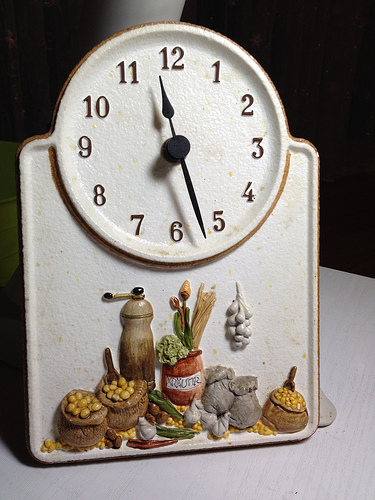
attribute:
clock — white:
[29, 44, 320, 455]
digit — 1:
[210, 55, 223, 86]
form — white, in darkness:
[2, 3, 374, 278]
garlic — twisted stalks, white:
[227, 279, 251, 351]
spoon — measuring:
[280, 366, 301, 387]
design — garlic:
[224, 270, 263, 350]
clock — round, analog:
[47, 20, 294, 275]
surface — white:
[34, 150, 317, 439]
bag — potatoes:
[56, 389, 107, 446]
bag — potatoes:
[95, 371, 149, 428]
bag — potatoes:
[260, 386, 307, 433]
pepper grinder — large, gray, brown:
[99, 285, 159, 391]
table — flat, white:
[321, 265, 374, 499]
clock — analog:
[46, 50, 261, 185]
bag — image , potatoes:
[57, 388, 114, 452]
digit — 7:
[130, 213, 143, 236]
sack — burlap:
[206, 368, 235, 413]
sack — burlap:
[228, 366, 257, 432]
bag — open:
[54, 403, 105, 446]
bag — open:
[97, 376, 145, 425]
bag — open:
[262, 389, 309, 435]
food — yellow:
[268, 389, 308, 415]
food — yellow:
[105, 374, 129, 409]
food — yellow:
[68, 393, 102, 413]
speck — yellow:
[221, 168, 233, 179]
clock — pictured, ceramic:
[14, 21, 339, 469]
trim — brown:
[277, 148, 291, 201]